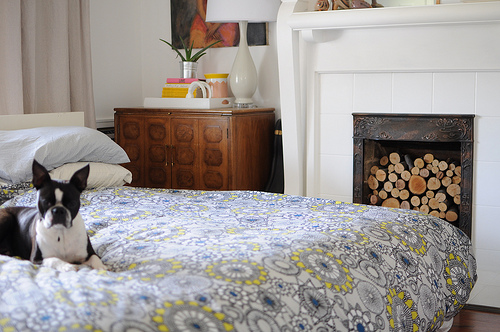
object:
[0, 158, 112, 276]
dog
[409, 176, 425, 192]
wood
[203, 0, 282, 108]
lamp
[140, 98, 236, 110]
tray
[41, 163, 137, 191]
pillow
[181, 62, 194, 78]
tin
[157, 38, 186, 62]
greens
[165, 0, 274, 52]
picture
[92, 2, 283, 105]
wall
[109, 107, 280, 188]
furniture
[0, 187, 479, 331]
portion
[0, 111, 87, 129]
top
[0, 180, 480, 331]
bed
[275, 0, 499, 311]
fireplace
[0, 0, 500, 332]
bedroom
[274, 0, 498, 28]
mantle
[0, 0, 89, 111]
curtain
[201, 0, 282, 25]
shade